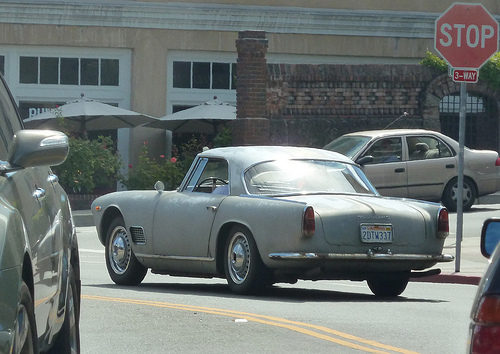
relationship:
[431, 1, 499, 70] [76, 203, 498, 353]
stop sign on side of road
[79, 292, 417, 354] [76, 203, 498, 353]
lines in middle of road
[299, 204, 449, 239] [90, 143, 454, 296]
tail lights on back of car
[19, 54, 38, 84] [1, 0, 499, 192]
window on side of building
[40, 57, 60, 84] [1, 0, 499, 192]
window on side of building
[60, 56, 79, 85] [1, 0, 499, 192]
window on side of building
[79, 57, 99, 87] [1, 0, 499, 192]
window on side of building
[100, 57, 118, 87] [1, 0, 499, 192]
window on side of building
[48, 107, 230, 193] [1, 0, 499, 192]
shrubs in front of building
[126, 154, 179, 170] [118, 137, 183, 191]
flowers growing on plant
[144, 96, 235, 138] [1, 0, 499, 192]
umbrella in front of building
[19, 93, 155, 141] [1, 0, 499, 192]
umbrella in front of building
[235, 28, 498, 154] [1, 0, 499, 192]
wall in front of building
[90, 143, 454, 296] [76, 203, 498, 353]
car on corner of road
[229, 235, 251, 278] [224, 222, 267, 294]
hubcap on side of tire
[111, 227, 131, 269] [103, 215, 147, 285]
hubcap on side of tire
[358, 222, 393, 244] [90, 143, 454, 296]
license plate on back of car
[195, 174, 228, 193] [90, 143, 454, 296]
steering wheel inside of car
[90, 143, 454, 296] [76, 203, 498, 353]
car stopped on road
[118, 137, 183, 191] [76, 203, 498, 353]
plant on side of road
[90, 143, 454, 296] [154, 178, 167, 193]
car has side mirror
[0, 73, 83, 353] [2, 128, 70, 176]
car has side mirror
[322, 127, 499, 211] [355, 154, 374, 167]
car has side mirror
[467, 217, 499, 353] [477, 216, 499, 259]
vehicle has side mirror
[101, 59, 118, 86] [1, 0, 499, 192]
window on front of building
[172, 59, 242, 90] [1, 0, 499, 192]
windows on front of building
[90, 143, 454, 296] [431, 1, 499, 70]
car stopped at stop sign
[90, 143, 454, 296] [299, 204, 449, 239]
car has tail lights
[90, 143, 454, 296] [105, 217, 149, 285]
car has tire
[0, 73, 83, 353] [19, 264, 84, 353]
car has wheels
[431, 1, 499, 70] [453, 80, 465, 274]
stop sign on top of post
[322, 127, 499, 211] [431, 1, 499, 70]
car behind stop sign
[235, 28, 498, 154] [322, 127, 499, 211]
wall behind car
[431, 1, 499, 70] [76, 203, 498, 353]
stop sign on corner of road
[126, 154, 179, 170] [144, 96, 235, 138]
flowers in front of umbrella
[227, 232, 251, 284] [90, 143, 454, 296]
hubcap on bottom of car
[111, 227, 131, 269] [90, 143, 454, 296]
hubcap on bottom of car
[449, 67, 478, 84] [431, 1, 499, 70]
3 way sign on bottom of stop sign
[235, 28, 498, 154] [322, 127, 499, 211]
wall next to car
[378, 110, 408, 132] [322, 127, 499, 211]
attenna on top of car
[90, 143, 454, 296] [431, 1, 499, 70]
car next to stop sign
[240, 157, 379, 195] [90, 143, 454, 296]
back window of car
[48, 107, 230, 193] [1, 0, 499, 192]
shrubs outside of building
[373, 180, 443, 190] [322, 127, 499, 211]
stripe on side of car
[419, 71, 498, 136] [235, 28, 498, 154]
archway part of wall